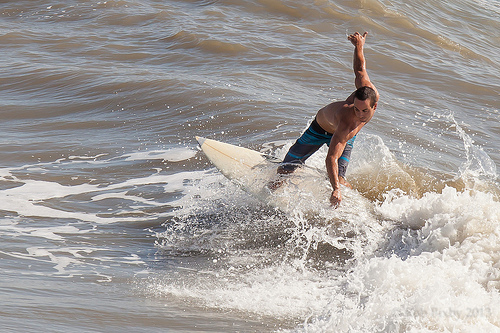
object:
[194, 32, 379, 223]
man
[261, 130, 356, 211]
over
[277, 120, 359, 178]
shorts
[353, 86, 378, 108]
hair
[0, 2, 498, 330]
water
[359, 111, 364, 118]
nose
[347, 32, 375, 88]
arm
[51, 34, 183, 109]
grey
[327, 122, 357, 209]
arms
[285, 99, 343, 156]
sides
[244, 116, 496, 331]
wave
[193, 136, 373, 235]
board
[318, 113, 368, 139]
off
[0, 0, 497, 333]
waves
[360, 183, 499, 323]
rough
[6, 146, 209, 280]
foam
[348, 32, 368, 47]
left hand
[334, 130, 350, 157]
right bicep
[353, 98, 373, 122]
face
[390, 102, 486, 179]
air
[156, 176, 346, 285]
air